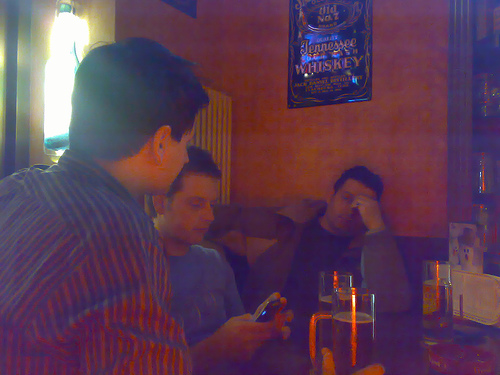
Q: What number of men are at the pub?
A: There are three men at the pub.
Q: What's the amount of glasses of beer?
A: There are three glasses of beer.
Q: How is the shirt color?
A: The shirt is light blue.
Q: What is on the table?
A: Drinking glasses.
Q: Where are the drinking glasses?
A: On the table.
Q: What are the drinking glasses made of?
A: Glass.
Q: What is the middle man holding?
A: A cell phone.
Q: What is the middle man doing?
A: Using a cell phone.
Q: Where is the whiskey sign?
A: On the wall.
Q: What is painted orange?
A: The walls.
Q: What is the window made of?
A: Glass.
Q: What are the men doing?
A: Sitting.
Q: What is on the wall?
A: A sign.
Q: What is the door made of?
A: Wood.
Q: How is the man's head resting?
A: On his hand.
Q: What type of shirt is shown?
A: Striped.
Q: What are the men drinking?
A: Beer.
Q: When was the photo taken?
A: Daytime.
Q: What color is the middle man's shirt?
A: Blue.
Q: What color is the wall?
A: Orange.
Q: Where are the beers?
A: On the table.